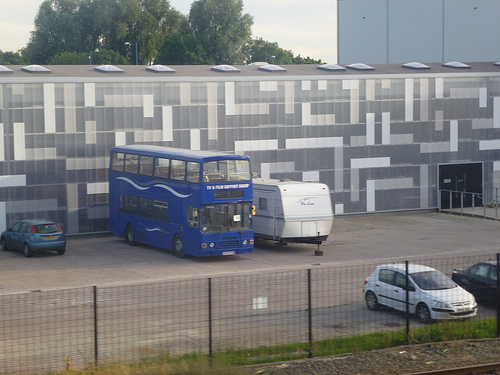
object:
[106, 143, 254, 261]
bus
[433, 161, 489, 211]
door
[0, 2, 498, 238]
building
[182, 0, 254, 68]
trees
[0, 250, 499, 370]
fence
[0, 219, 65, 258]
car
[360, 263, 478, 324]
car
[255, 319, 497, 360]
grass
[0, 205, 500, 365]
ground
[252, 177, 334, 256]
camper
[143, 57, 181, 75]
skylights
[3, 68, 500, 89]
roof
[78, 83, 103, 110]
square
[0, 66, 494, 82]
panels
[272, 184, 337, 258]
trailer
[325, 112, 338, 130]
stone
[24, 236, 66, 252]
plate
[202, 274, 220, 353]
pole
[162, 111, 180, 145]
strip